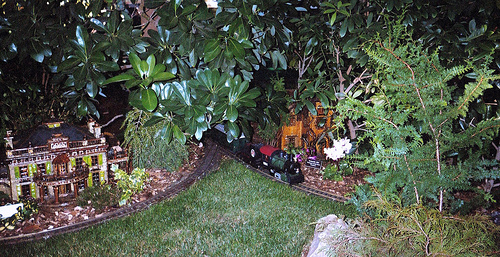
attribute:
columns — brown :
[20, 180, 108, 201]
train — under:
[217, 125, 300, 184]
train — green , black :
[230, 126, 280, 176]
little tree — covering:
[339, 47, 469, 215]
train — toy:
[253, 104, 341, 207]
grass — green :
[1, 147, 376, 254]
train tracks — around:
[0, 139, 365, 244]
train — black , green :
[259, 141, 308, 183]